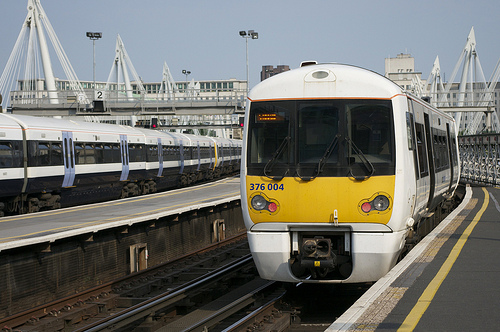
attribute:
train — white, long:
[231, 66, 468, 283]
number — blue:
[247, 181, 287, 193]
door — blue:
[58, 129, 83, 190]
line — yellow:
[399, 187, 493, 330]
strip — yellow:
[242, 174, 398, 227]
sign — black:
[254, 109, 292, 125]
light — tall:
[372, 195, 390, 213]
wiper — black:
[308, 130, 345, 176]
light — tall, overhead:
[234, 29, 263, 91]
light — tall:
[83, 33, 108, 83]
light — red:
[150, 119, 165, 134]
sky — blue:
[293, 5, 451, 53]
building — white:
[19, 76, 249, 119]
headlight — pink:
[355, 198, 372, 218]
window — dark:
[301, 106, 345, 178]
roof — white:
[1, 116, 162, 147]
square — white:
[94, 89, 106, 101]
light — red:
[235, 117, 247, 133]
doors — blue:
[116, 136, 139, 184]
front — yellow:
[237, 176, 403, 282]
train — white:
[0, 105, 246, 217]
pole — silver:
[242, 41, 261, 85]